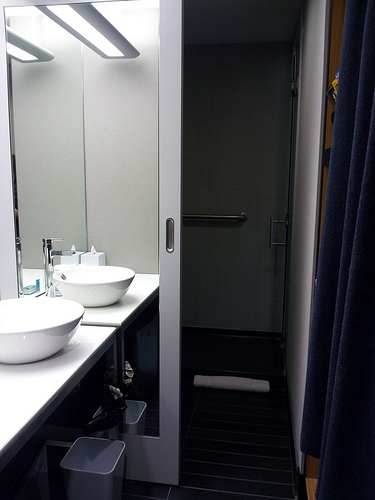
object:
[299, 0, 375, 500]
curtain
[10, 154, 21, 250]
people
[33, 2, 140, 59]
light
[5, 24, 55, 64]
light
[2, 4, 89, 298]
mirror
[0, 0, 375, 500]
bathroom